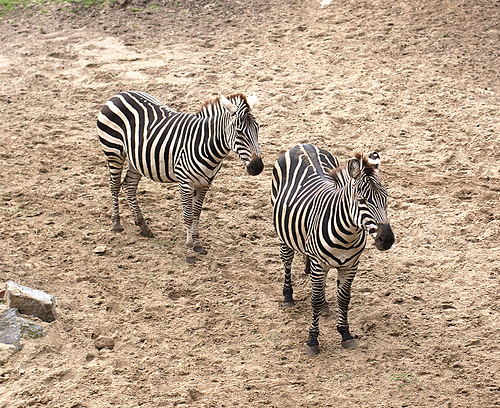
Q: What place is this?
A: It is a field.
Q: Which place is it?
A: It is a field.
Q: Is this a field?
A: Yes, it is a field.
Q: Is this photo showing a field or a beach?
A: It is showing a field.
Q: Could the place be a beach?
A: No, it is a field.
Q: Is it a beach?
A: No, it is a field.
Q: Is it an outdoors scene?
A: Yes, it is outdoors.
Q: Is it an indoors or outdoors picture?
A: It is outdoors.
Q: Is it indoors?
A: No, it is outdoors.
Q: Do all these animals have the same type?
A: Yes, all the animals are zebras.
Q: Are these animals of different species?
A: No, all the animals are zebras.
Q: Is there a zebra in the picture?
A: Yes, there is a zebra.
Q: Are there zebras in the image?
A: Yes, there is a zebra.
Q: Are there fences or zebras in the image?
A: Yes, there is a zebra.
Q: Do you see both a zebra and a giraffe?
A: No, there is a zebra but no giraffes.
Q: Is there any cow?
A: No, there are no cows.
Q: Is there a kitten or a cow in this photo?
A: No, there are no cows or kittens.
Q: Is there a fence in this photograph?
A: No, there are no fences.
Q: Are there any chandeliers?
A: No, there are no chandeliers.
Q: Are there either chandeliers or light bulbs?
A: No, there are no chandeliers or light bulbs.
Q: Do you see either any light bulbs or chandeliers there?
A: No, there are no chandeliers or light bulbs.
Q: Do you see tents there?
A: No, there are no tents.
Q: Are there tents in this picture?
A: No, there are no tents.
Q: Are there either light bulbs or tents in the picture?
A: No, there are no tents or light bulbs.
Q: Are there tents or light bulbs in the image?
A: No, there are no tents or light bulbs.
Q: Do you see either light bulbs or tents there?
A: No, there are no tents or light bulbs.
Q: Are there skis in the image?
A: No, there are no skis.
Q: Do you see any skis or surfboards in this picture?
A: No, there are no skis or surfboards.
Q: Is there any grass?
A: Yes, there is grass.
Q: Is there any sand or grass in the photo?
A: Yes, there is grass.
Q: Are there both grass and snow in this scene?
A: No, there is grass but no snow.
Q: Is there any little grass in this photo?
A: Yes, there is little grass.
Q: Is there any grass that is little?
A: Yes, there is grass that is little.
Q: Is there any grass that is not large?
A: Yes, there is little grass.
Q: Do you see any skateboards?
A: No, there are no skateboards.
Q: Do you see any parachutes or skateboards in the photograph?
A: No, there are no skateboards or parachutes.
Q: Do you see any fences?
A: No, there are no fences.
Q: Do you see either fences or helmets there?
A: No, there are no fences or helmets.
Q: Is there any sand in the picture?
A: Yes, there is sand.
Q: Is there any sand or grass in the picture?
A: Yes, there is sand.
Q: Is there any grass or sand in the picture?
A: Yes, there is sand.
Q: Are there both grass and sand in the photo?
A: Yes, there are both sand and grass.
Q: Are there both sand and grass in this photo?
A: Yes, there are both sand and grass.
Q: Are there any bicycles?
A: No, there are no bicycles.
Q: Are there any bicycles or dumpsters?
A: No, there are no bicycles or dumpsters.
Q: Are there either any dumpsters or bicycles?
A: No, there are no bicycles or dumpsters.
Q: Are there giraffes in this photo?
A: No, there are no giraffes.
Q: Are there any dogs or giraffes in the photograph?
A: No, there are no giraffes or dogs.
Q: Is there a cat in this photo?
A: No, there are no cats.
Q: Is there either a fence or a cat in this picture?
A: No, there are no cats or fences.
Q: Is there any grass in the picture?
A: Yes, there is grass.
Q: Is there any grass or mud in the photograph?
A: Yes, there is grass.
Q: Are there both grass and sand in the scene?
A: Yes, there are both grass and sand.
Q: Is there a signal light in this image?
A: No, there are no traffic lights.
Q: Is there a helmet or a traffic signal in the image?
A: No, there are no traffic lights or helmets.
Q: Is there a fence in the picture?
A: No, there are no fences.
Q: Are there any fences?
A: No, there are no fences.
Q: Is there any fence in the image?
A: No, there are no fences.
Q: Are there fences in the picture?
A: No, there are no fences.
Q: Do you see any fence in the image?
A: No, there are no fences.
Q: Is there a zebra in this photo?
A: Yes, there is a zebra.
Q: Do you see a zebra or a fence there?
A: Yes, there is a zebra.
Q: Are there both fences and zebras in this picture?
A: No, there is a zebra but no fences.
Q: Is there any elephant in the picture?
A: No, there are no elephants.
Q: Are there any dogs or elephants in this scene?
A: No, there are no elephants or dogs.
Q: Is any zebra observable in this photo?
A: Yes, there are zebras.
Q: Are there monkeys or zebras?
A: Yes, there are zebras.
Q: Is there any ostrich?
A: No, there are no ostriches.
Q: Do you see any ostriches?
A: No, there are no ostriches.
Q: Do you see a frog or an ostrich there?
A: No, there are no ostriches or frogs.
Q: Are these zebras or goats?
A: These are zebras.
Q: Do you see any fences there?
A: No, there are no fences.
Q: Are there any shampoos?
A: No, there are no shampoos.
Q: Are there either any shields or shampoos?
A: No, there are no shampoos or shields.